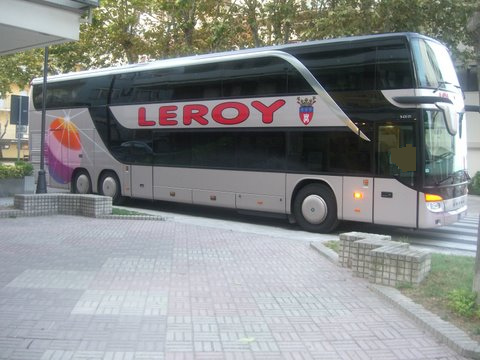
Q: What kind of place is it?
A: It is a sidewalk.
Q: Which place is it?
A: It is a sidewalk.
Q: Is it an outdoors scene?
A: Yes, it is outdoors.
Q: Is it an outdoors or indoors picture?
A: It is outdoors.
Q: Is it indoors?
A: No, it is outdoors.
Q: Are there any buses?
A: Yes, there is a bus.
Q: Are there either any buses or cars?
A: Yes, there is a bus.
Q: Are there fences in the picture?
A: No, there are no fences.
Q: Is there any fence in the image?
A: No, there are no fences.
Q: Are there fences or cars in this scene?
A: No, there are no fences or cars.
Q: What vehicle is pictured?
A: The vehicle is a bus.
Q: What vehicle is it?
A: The vehicle is a bus.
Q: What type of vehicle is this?
A: That is a bus.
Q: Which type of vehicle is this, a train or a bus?
A: That is a bus.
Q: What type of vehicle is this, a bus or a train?
A: That is a bus.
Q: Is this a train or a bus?
A: This is a bus.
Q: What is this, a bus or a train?
A: This is a bus.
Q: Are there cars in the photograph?
A: No, there are no cars.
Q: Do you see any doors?
A: Yes, there is a door.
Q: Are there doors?
A: Yes, there is a door.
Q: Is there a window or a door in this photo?
A: Yes, there is a door.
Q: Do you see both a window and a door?
A: Yes, there are both a door and a window.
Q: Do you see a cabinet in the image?
A: No, there are no cabinets.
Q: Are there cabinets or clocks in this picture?
A: No, there are no cabinets or clocks.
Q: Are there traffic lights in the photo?
A: No, there are no traffic lights.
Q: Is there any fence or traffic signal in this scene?
A: No, there are no traffic lights or fences.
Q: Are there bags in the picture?
A: No, there are no bags.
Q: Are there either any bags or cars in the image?
A: No, there are no bags or cars.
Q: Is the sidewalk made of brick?
A: Yes, the sidewalk is made of brick.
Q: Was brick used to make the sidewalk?
A: Yes, the sidewalk is made of brick.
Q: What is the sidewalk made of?
A: The sidewalk is made of brick.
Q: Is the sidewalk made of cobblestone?
A: No, the sidewalk is made of brick.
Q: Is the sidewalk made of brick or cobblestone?
A: The sidewalk is made of brick.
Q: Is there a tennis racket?
A: No, there are no rackets.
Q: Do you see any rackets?
A: No, there are no rackets.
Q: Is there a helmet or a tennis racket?
A: No, there are no rackets or helmets.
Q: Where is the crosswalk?
A: The crosswalk is on the street.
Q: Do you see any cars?
A: No, there are no cars.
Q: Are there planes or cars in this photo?
A: No, there are no cars or planes.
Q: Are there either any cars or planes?
A: No, there are no cars or planes.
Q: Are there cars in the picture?
A: No, there are no cars.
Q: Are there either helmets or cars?
A: No, there are no cars or helmets.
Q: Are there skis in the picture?
A: No, there are no skis.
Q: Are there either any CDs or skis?
A: No, there are no skis or cds.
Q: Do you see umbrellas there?
A: No, there are no umbrellas.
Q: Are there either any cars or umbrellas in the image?
A: No, there are no umbrellas or cars.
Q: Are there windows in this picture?
A: Yes, there is a window.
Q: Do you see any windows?
A: Yes, there is a window.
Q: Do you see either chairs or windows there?
A: Yes, there is a window.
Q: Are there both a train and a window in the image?
A: No, there is a window but no trains.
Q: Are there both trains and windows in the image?
A: No, there is a window but no trains.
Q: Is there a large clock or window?
A: Yes, there is a large window.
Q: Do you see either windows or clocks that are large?
A: Yes, the window is large.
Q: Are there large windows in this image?
A: Yes, there is a large window.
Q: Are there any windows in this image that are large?
A: Yes, there is a window that is large.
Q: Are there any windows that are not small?
A: Yes, there is a large window.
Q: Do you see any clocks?
A: No, there are no clocks.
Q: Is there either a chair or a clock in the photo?
A: No, there are no clocks or chairs.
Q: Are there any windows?
A: Yes, there is a window.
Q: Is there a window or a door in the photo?
A: Yes, there is a window.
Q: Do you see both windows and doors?
A: Yes, there are both a window and a door.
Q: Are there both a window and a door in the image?
A: Yes, there are both a window and a door.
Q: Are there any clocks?
A: No, there are no clocks.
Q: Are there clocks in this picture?
A: No, there are no clocks.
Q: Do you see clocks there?
A: No, there are no clocks.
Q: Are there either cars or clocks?
A: No, there are no clocks or cars.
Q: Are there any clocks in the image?
A: No, there are no clocks.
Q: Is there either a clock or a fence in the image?
A: No, there are no clocks or fences.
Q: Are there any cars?
A: No, there are no cars.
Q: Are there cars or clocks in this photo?
A: No, there are no cars or clocks.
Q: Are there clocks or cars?
A: No, there are no cars or clocks.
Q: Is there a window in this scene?
A: Yes, there is a window.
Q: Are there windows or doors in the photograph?
A: Yes, there is a window.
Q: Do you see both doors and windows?
A: Yes, there are both a window and a door.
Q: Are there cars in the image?
A: No, there are no cars.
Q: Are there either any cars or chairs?
A: No, there are no cars or chairs.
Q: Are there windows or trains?
A: Yes, there is a window.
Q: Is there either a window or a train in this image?
A: Yes, there is a window.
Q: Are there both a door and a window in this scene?
A: Yes, there are both a window and a door.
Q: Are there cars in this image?
A: No, there are no cars.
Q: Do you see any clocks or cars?
A: No, there are no cars or clocks.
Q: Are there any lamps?
A: No, there are no lamps.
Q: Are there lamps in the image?
A: No, there are no lamps.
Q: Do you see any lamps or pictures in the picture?
A: No, there are no lamps or pictures.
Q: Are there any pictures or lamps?
A: No, there are no lamps or pictures.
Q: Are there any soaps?
A: No, there are no soaps.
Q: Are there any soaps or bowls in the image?
A: No, there are no soaps or bowls.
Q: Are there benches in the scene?
A: No, there are no benches.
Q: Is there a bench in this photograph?
A: No, there are no benches.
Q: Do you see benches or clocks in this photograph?
A: No, there are no benches or clocks.